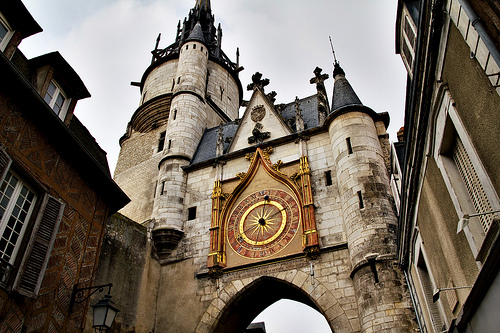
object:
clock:
[205, 146, 320, 279]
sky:
[0, 0, 408, 182]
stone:
[180, 130, 197, 141]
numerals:
[250, 193, 256, 200]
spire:
[326, 61, 364, 114]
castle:
[113, 1, 424, 333]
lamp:
[66, 282, 124, 333]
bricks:
[345, 193, 360, 208]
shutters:
[8, 194, 65, 299]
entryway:
[210, 274, 336, 333]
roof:
[188, 118, 242, 165]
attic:
[24, 46, 94, 130]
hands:
[262, 193, 269, 218]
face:
[224, 161, 304, 270]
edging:
[299, 155, 320, 259]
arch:
[217, 146, 308, 271]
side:
[0, 99, 100, 333]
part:
[83, 17, 103, 36]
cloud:
[72, 8, 136, 33]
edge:
[206, 178, 227, 279]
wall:
[78, 210, 151, 333]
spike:
[328, 34, 340, 65]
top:
[331, 63, 347, 79]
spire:
[177, 20, 208, 47]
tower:
[148, 19, 211, 258]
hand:
[265, 205, 290, 221]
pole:
[64, 281, 78, 319]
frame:
[0, 169, 40, 266]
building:
[0, 0, 132, 333]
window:
[0, 145, 68, 301]